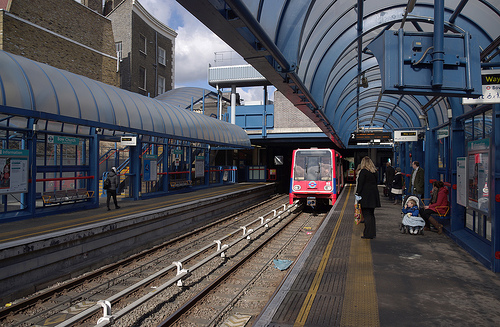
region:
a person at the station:
[352, 142, 379, 238]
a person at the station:
[398, 195, 419, 224]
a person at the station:
[425, 180, 455, 230]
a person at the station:
[406, 156, 428, 200]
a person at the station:
[389, 165, 409, 207]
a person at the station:
[376, 152, 395, 190]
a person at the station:
[101, 166, 123, 199]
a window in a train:
[290, 142, 332, 187]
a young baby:
[396, 187, 428, 243]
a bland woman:
[354, 147, 384, 244]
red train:
[284, 143, 346, 213]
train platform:
[299, 248, 440, 323]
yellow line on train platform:
[345, 258, 385, 325]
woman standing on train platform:
[350, 153, 387, 243]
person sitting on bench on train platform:
[421, 176, 453, 238]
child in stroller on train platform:
[389, 195, 426, 237]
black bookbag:
[96, 175, 114, 192]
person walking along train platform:
[102, 163, 124, 211]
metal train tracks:
[265, 215, 305, 247]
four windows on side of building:
[112, 4, 179, 84]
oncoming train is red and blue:
[277, 126, 365, 227]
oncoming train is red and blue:
[245, 95, 381, 255]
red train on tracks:
[277, 107, 367, 224]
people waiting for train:
[334, 151, 442, 290]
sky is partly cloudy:
[150, 19, 277, 107]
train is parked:
[254, 139, 388, 307]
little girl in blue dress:
[371, 194, 458, 260]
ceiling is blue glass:
[247, 16, 477, 173]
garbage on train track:
[236, 222, 345, 301]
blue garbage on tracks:
[228, 219, 340, 309]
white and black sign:
[388, 119, 448, 173]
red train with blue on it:
[251, 139, 369, 256]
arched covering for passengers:
[6, 47, 266, 230]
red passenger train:
[276, 130, 348, 229]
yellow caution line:
[289, 178, 380, 323]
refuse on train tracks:
[258, 230, 295, 279]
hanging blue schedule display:
[371, 6, 486, 116]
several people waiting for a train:
[342, 132, 460, 248]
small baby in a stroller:
[392, 180, 427, 240]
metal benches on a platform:
[28, 164, 210, 215]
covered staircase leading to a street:
[135, 72, 238, 194]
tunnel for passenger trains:
[211, 107, 396, 247]